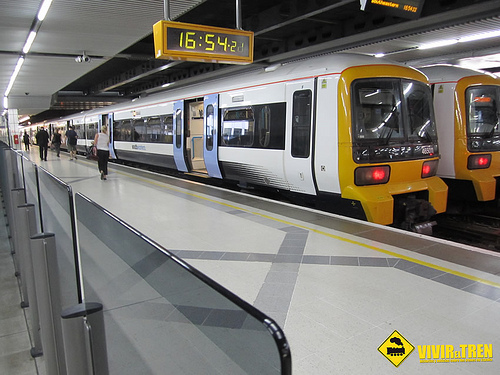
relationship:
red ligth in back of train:
[354, 167, 389, 184] [27, 44, 452, 233]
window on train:
[352, 77, 439, 163] [0, 43, 457, 240]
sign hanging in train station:
[146, 15, 268, 72] [0, 55, 495, 250]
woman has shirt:
[93, 124, 110, 179] [98, 131, 108, 151]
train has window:
[27, 44, 452, 233] [466, 85, 499, 135]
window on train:
[110, 110, 176, 148] [0, 43, 457, 240]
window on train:
[110, 110, 176, 148] [27, 44, 452, 233]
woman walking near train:
[93, 124, 110, 179] [27, 44, 452, 233]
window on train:
[468, 83, 498, 145] [22, 51, 451, 236]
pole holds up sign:
[156, 0, 175, 19] [148, 20, 256, 65]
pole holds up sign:
[228, 0, 248, 28] [148, 20, 256, 65]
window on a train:
[218, 104, 255, 148] [61, 61, 454, 222]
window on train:
[173, 106, 183, 150] [27, 44, 452, 233]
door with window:
[201, 91, 223, 183] [206, 103, 212, 153]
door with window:
[170, 96, 187, 177] [175, 109, 180, 151]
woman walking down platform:
[93, 124, 110, 179] [0, 128, 497, 373]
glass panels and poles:
[16, 135, 303, 371] [2, 152, 109, 370]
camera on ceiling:
[74, 54, 89, 64] [4, 1, 499, 112]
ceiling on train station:
[4, 1, 499, 112] [4, 4, 494, 373]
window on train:
[220, 108, 258, 145] [27, 44, 452, 233]